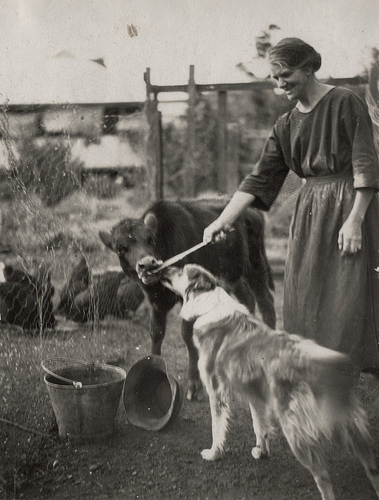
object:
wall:
[273, 109, 312, 114]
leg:
[200, 384, 231, 462]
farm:
[0, 33, 374, 498]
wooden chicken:
[143, 64, 275, 206]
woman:
[202, 36, 379, 377]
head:
[99, 212, 163, 286]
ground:
[301, 104, 316, 125]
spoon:
[147, 226, 236, 275]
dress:
[180, 285, 249, 330]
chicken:
[67, 271, 124, 323]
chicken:
[112, 277, 145, 318]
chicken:
[53, 256, 91, 314]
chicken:
[2, 263, 54, 297]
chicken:
[0, 281, 58, 333]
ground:
[1, 249, 377, 497]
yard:
[81, 420, 246, 494]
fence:
[0, 0, 379, 385]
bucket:
[40, 354, 127, 441]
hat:
[123, 355, 184, 433]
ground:
[1, 449, 31, 476]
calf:
[98, 198, 276, 400]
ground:
[35, 427, 223, 497]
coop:
[8, 210, 144, 356]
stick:
[153, 228, 235, 275]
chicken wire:
[18, 223, 146, 339]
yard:
[4, 199, 156, 379]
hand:
[203, 223, 227, 246]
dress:
[283, 180, 378, 373]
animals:
[159, 262, 378, 499]